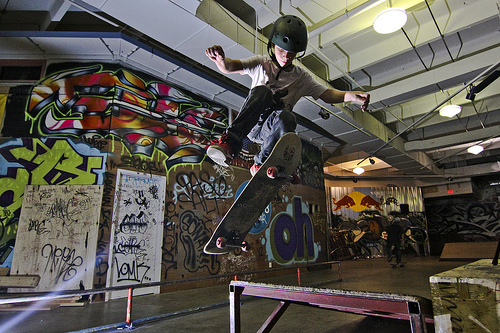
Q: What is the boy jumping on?
A: A skateboard.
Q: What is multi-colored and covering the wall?
A: Graffiti.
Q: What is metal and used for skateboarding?
A: A ramp.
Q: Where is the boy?
A: In the air.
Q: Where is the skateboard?
A: In the air.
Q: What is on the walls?
A: Graffiti.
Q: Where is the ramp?
A: Under the boy.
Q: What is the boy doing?
A: Jumping.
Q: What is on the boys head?
A: A helmet.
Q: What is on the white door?
A: Graffiti.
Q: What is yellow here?
A: Graffiti.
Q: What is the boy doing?
A: A trick.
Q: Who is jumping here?
A: The boy.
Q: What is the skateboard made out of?
A: Wood.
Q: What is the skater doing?
A: Tricks.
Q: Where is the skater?
A: In the air.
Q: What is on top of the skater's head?
A: A helmet.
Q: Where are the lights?
A: On the ceiling.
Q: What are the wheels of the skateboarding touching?
A: Air.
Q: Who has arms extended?
A: The skater.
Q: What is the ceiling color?
A: White.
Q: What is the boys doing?
A: Skating.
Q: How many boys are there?
A: 2.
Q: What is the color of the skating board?
A: Black.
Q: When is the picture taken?
A: Daytime.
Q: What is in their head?
A: Helmet.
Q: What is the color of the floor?
A: Brown.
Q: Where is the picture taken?
A: A garage.